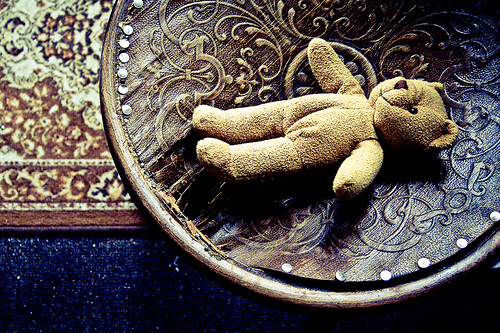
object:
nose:
[393, 80, 407, 90]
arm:
[306, 36, 367, 96]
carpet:
[0, 236, 500, 332]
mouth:
[376, 82, 396, 106]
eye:
[404, 104, 421, 114]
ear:
[426, 117, 459, 151]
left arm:
[330, 138, 383, 201]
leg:
[228, 99, 283, 140]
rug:
[0, 0, 500, 331]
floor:
[0, 0, 500, 331]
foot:
[193, 136, 237, 182]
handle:
[99, 0, 499, 309]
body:
[189, 38, 384, 195]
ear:
[415, 80, 446, 93]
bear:
[190, 36, 458, 198]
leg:
[229, 136, 302, 181]